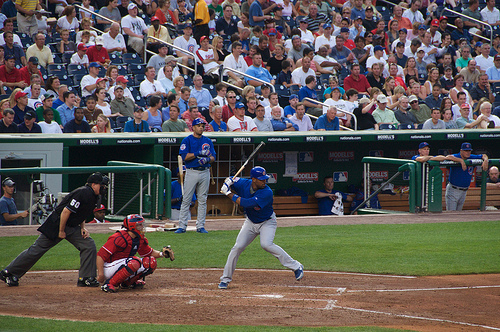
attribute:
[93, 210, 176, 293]
catcher — dressed, calling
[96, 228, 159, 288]
uniform — red, white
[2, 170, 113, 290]
umpire — leaning forward, making call, watching, officiating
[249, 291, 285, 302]
home plate — white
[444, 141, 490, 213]
man — leaning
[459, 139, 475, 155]
hat — blue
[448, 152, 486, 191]
shirt — blue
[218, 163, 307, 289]
batter — prepared, hitting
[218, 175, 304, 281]
uniform — blue, grey, white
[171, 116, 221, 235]
man — waiting, waiting to bat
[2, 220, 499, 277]
grass — green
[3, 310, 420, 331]
grass — green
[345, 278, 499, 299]
line — chalk, white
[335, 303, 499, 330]
line — chalk, white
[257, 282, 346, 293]
line — chalk, white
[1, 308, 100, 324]
line — chalk, white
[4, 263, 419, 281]
line — chalk, white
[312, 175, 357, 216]
man — sitting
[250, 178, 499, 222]
bench — wooden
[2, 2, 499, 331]
scene — baseball game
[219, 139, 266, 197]
bat — white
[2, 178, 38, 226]
cameraman — filming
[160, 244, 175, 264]
mitt — leather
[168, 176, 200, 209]
jersey — blue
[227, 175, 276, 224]
jersey — blue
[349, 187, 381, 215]
jersey — blue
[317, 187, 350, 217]
jersey — blue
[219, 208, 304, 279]
pants — grey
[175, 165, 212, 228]
pants — grey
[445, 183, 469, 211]
pants — grey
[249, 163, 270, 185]
helmet — blue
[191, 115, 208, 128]
helmet — blue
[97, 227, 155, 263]
jersey — red, blue red, white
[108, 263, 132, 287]
shin guard — red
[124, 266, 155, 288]
shin guard — red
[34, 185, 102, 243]
shirt — black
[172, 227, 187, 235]
spikes — blue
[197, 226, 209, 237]
spikes — blue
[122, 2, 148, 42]
fan — sitting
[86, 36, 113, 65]
fan — sitting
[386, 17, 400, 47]
fan — sitting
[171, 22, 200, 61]
fan — sitting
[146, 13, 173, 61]
fan — sitting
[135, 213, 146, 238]
face mask — red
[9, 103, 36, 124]
shirt — blue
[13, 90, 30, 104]
hat — red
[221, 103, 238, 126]
shirt — red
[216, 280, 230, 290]
shoe — blue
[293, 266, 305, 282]
shoe — blue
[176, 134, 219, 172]
shirt — cubs shirt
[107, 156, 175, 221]
gate — open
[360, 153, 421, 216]
gate — open